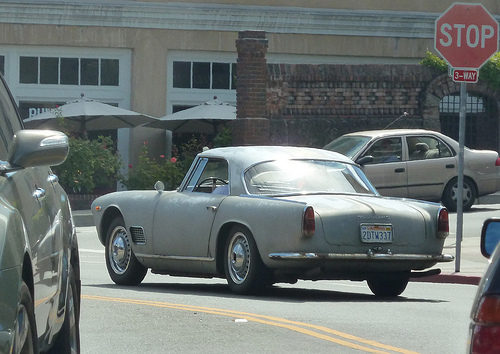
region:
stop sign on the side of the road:
[439, 4, 494, 102]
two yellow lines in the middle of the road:
[87, 284, 407, 331]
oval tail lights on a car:
[287, 201, 322, 251]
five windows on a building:
[21, 44, 139, 108]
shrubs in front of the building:
[48, 130, 129, 199]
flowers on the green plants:
[124, 139, 181, 195]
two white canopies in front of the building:
[16, 90, 235, 152]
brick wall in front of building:
[272, 53, 448, 134]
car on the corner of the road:
[99, 144, 427, 286]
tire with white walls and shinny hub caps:
[214, 227, 259, 294]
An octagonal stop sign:
[432, 5, 499, 67]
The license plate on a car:
[357, 219, 392, 242]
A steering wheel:
[197, 172, 227, 190]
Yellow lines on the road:
[80, 287, 407, 352]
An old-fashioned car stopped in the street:
[95, 148, 445, 293]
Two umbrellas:
[28, 92, 240, 140]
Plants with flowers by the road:
[60, 133, 197, 196]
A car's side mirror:
[152, 179, 168, 193]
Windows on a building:
[170, 55, 242, 95]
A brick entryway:
[240, 43, 497, 150]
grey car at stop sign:
[137, 137, 400, 276]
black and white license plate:
[354, 218, 400, 258]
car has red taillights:
[286, 209, 466, 243]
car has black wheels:
[93, 206, 275, 286]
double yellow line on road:
[92, 286, 356, 345]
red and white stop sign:
[429, 16, 486, 68]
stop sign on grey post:
[417, 86, 470, 276]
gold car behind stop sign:
[335, 109, 499, 215]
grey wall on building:
[5, 30, 215, 145]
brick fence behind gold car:
[254, 18, 499, 145]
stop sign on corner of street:
[435, 0, 498, 67]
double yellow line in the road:
[154, 299, 361, 347]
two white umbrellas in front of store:
[33, 90, 247, 138]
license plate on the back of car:
[359, 221, 405, 251]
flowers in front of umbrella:
[121, 132, 196, 203]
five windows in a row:
[13, 46, 135, 94]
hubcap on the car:
[223, 236, 256, 288]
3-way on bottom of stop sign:
[451, 63, 484, 84]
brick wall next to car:
[216, 23, 457, 153]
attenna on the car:
[375, 101, 425, 133]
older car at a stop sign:
[83, 138, 453, 300]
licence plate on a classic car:
[354, 213, 394, 248]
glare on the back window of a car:
[241, 154, 372, 203]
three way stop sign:
[433, 0, 499, 91]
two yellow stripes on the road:
[78, 285, 418, 352]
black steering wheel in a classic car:
[193, 172, 230, 193]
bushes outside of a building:
[31, 125, 213, 192]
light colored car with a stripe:
[307, 123, 499, 212]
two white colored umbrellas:
[16, 90, 243, 142]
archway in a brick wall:
[420, 73, 496, 168]